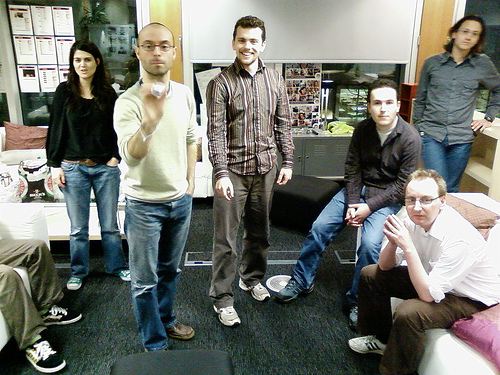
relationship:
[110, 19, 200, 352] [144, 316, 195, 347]
man has shoes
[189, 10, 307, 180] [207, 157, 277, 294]
man has pants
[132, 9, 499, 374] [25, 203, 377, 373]
men on green carpet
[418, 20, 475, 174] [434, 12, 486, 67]
man has brown hair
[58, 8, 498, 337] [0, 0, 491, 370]
people inside office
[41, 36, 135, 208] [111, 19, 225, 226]
woman behind man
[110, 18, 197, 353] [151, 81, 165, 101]
person holding controller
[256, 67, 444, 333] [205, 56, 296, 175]
man wearing shirt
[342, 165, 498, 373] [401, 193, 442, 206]
man wearing glasses